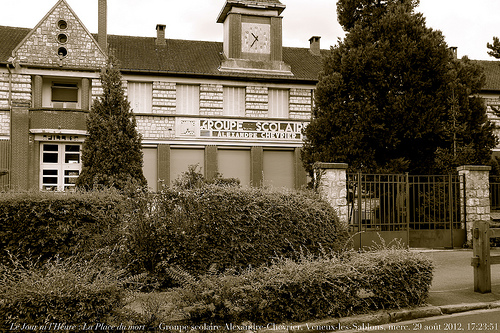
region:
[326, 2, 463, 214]
This is a tree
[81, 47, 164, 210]
This is a tree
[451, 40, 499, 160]
This is a tree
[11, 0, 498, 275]
This is a house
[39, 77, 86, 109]
This is a window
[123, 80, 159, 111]
This is a window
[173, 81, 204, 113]
This is a window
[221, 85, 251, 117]
This is a window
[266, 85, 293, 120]
This is a window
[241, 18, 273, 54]
This is a clock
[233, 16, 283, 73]
Clock on top of building.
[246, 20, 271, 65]
Hands on clock are black.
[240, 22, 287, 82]
Face on clock is white.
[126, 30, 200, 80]
Roof on building is dark.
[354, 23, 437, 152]
Large tree in front of building.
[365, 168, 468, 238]
Fence slightly open in front of building.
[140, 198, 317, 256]
Large bush in front of building.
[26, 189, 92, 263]
Large bush in front of building.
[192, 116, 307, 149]
White letters on front of building.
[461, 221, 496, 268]
Wood fence in front of building.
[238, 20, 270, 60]
two hands on a clock face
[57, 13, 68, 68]
three verticle circles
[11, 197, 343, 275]
row of hedges in front of a tree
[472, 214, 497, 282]
wooden post of a fence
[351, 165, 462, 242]
metal gate in front of a house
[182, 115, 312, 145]
sign on the front of a building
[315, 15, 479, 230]
big tree behind the gate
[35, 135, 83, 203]
white outlined entranceway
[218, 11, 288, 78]
clock on the front of a cuppola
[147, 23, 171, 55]
small chimney on the roof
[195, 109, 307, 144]
a sign on a building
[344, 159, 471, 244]
a gate into the building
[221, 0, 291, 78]
a clock tower over the sign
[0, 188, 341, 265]
a hedge by the gate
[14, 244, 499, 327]
a sidewalk in front of the gate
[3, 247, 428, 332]
a hedge in front of the sidewalk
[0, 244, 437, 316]
this hedge is smaller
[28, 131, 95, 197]
a window in the building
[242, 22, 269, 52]
black hands on the clock face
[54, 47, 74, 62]
a round window in the building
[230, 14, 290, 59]
a clock on a building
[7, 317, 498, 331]
white writing along the bottom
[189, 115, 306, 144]
white letters on the building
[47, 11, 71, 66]
three circles on top of eachother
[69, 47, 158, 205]
a narrow pine tree in front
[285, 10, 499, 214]
a wide tree to the right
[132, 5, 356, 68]
two vents on the roof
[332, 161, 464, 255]
an opening in the gate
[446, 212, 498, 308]
part of a wooden fence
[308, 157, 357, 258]
stone pillar around gate entrance